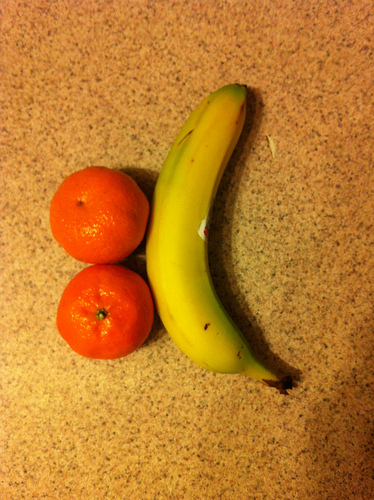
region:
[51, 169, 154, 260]
the clementine is orange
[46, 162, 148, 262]
the clementine is round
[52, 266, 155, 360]
the clementine is rough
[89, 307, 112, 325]
the stem on the clementine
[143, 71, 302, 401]
the banana is green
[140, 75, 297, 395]
the banana is yellow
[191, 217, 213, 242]
a sticker on the banana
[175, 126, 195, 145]
a brown spot on the banana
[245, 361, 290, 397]
the banana stem is brown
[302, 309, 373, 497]
a shadow on the granite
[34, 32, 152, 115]
Floor is brown color.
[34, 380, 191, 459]
Black spots on floor.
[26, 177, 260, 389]
Fruits are on floor.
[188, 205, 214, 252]
Sticker is on banana.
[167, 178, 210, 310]
Banana is yellow color.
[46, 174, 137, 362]
Two oranges are near the banana.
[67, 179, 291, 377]
Shadow falls on floor.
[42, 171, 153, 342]
Oranges are orange color.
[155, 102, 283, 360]
One banana is on floor.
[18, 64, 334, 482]
Picture is taken indoor.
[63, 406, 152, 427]
this is the table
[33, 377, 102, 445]
the table is wooden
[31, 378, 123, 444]
the table is brown in color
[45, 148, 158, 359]
these are some oranges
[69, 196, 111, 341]
the oranges are shiny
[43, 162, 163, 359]
the oranges are round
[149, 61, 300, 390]
this is a banana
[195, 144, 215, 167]
the banana is yellow in color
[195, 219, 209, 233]
this is a sticker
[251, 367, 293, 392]
this is a stalk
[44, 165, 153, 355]
two orange tangerines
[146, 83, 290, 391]
yellow banana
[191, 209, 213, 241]
white sticker on the yellow banana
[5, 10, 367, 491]
countertop fruit is on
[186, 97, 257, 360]
brown spots on the banana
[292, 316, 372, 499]
shadow on the countertop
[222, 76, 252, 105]
green end of the banana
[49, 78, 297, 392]
banana and tangerines on the countertop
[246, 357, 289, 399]
stem of the banana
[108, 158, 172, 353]
shadows of the tangerines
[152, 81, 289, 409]
a banana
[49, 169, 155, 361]
two oranges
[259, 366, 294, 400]
the stem of the banana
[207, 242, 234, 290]
a shadow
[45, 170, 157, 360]
the fruit is orange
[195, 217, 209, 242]
a sticker on the banana peel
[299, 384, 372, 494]
a shadow on the counter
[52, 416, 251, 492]
the counter top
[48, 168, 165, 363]
two small oranges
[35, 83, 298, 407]
the pieces of fruit